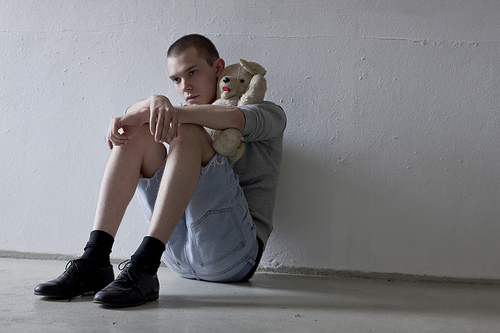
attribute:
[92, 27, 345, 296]
man — sitting, holding, young, alone, frowning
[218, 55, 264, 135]
bear — stuffed, bown, teddy, white, held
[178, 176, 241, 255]
shorts — denim, blue, jean, jeans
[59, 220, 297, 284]
socks — slouched, black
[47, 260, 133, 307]
shoes — lace-up, black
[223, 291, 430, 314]
concrete — white, gray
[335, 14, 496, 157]
wall — spackeled, white, cement, smooth, painted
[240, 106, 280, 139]
sleve — long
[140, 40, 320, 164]
boy — sitting, wearing, holding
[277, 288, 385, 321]
floor — gray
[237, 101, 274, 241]
shirt — gray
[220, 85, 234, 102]
tongue — red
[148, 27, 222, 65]
hair — dark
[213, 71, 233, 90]
nose — black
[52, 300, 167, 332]
ground — cement